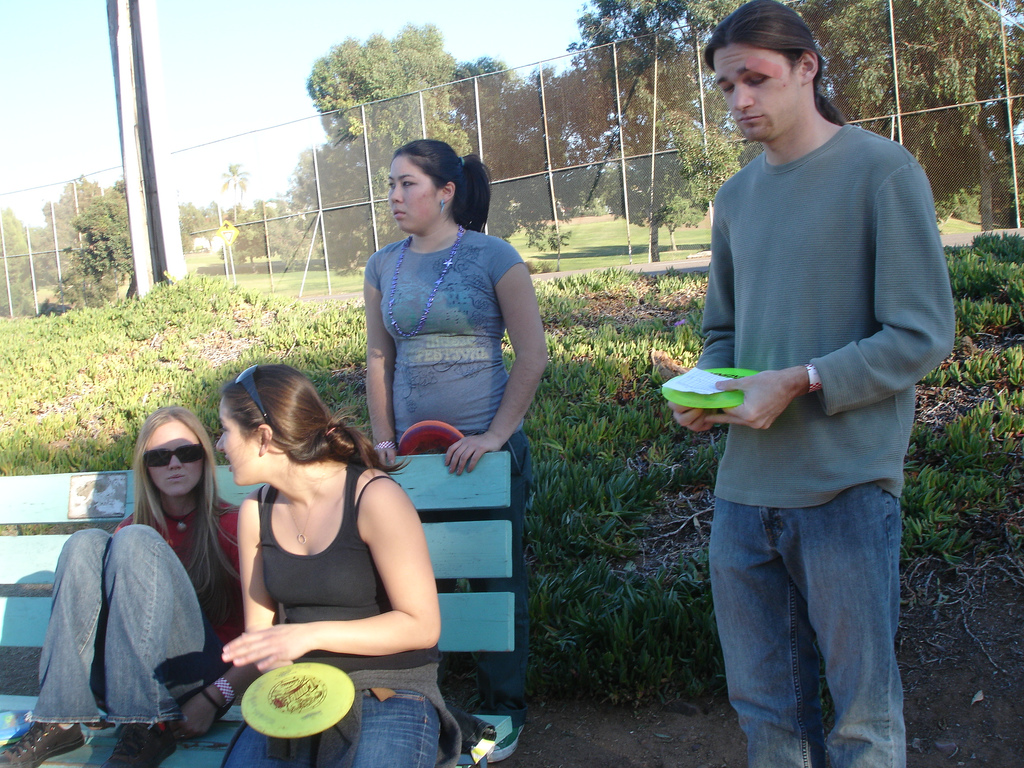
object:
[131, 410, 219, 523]
girl head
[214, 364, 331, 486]
girl head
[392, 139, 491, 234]
hair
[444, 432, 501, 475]
girl hand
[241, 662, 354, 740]
frisbee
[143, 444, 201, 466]
glasses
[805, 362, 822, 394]
bracelet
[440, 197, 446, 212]
earrings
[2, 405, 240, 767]
woman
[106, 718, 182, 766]
shoe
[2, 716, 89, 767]
shoe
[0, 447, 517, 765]
bench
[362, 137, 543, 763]
woman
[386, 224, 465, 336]
necklace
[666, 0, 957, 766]
man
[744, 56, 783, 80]
band-aid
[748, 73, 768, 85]
eye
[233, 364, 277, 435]
sunglasses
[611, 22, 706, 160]
fence section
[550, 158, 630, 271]
fence section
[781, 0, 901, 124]
fence section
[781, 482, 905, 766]
leg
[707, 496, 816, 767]
leg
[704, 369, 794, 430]
hand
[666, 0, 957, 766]
boy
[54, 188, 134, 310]
tree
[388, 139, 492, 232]
head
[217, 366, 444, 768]
girl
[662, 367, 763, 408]
frisbee